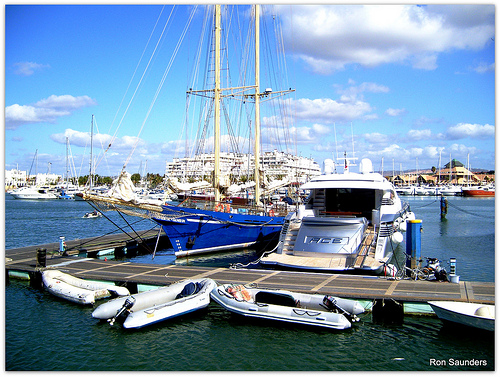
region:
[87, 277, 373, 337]
inflatable boats on the water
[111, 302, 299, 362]
the water is calm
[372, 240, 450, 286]
a bike is parked on the walkway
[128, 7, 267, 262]
the boat is blue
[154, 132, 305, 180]
a building in the background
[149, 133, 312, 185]
the building is white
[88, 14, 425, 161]
the sky is partly cloudy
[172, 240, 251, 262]
reflection of the boat in the water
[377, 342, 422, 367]
a white object in the water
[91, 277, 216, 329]
boat is docked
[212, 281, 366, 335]
boat is docked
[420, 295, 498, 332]
boat is docked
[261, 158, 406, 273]
boat is docked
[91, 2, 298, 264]
boat is docked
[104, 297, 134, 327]
motor is up out of the water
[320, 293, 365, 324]
motor is up out of the water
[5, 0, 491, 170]
sky is filled with clouds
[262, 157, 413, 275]
boat is empty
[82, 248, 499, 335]
A long gray pier.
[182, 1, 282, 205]
Two large boat masts.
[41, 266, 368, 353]
Three small sized boats in the harbor.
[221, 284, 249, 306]
An orange and white life jacket.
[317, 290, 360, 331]
A small boat engine.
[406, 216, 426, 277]
A blue and yellow support pillar.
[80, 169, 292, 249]
A bright blue ship in the bay.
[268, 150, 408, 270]
A medium sized boat in the bay.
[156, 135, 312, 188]
A large white building on the shore.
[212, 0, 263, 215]
these are two poles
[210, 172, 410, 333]
this is a boat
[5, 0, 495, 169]
this is the sky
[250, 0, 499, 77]
these are the clouds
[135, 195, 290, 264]
this is a blue boat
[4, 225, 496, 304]
this is a ramp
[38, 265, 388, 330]
these are water rafts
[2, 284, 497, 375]
this is green water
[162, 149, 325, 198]
this is a white building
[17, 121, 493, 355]
boats in a marina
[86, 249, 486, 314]
pier by the boats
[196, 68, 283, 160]
masts of a boat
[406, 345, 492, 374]
copyright of a photographer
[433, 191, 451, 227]
pole in the water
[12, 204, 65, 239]
water of a marina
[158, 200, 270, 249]
ropes to a dock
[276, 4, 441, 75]
white cloud in the sky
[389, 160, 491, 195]
buildings by the edge of dock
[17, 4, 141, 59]
blue sky in the distance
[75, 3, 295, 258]
Boat with the bluest bottom and two tall masts.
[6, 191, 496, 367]
Blue and green body of water.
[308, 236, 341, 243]
The word ACE on a boat.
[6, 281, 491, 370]
Green area of water.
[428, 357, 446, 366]
The white name Ron.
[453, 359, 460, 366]
Small a in Saunders.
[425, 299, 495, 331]
Small white boat over Saunders.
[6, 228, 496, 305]
A long L shaped grey dock.